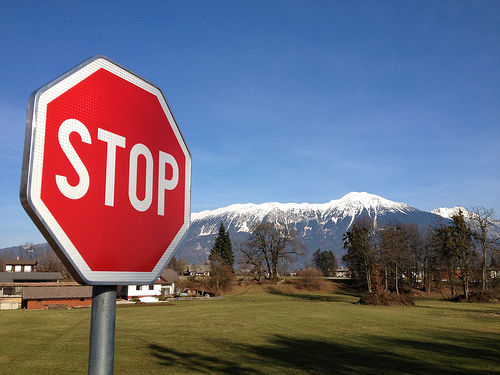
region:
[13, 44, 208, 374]
A sign is in the foreground.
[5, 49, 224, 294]
The sign is a stop sign.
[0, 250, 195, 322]
Buildings are behind the sign.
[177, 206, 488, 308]
Trees are next to the buildings.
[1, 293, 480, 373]
A green lawn is in front of the buildings.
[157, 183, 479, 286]
A mountain is in the background.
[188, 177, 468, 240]
The mountain is topped with snow.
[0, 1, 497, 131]
The sky is blue.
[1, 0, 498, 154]
The sky is cloudless.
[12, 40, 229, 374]
The sign is made of metal.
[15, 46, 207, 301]
Red stop sign.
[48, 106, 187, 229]
Stop is printed on the sign.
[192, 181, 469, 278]
Mountains are snow-capped.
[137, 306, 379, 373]
Shadows on the grass.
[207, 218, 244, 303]
Evergreen tree.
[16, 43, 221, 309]
The stop sign is an octagon.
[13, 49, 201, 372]
The sign is made of metal.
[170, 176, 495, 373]
The mountains are in the background.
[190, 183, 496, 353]
The grass is in the foreground.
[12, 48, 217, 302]
The sign has a white border.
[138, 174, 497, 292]
mountains are grey and white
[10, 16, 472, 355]
Picture is taken outside.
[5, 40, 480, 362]
Picture taken during the day.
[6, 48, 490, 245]
The sky is blue.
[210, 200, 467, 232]
Snow covers the mountain tops.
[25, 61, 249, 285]
A stop sign.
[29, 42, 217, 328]
Stop sign is red and white.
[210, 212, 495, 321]
Green trees.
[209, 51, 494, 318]
The sun is out.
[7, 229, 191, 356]
A house is on the left of the picture.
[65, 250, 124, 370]
A pole holds the stop sign.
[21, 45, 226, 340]
a big bright red stop sign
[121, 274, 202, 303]
there is a house a little ways away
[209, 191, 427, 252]
the mountains are snowcapped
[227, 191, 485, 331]
the mountains seem very tall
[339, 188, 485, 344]
a small grove of trees stands nearby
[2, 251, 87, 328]
several other homes and buildings are in the area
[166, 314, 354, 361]
the grass is nice & green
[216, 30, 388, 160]
the sky is so very blue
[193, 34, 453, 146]
the sky is amazingly clear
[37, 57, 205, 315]
the stop sign is red with white letters